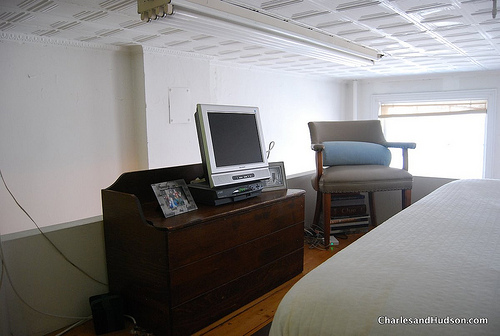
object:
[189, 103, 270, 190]
television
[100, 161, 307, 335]
dresser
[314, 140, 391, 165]
pillow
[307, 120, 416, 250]
chair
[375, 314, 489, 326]
name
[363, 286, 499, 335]
corner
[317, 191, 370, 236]
books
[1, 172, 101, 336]
wire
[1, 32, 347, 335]
wall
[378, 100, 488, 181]
window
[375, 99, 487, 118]
blinds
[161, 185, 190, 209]
picture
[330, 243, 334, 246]
light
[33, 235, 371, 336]
floor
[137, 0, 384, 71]
light fixture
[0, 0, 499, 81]
ceiling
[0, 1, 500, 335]
room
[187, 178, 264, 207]
cable box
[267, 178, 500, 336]
bed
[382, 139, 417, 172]
left armrest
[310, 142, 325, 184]
right armrest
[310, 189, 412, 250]
legs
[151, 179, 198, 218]
picture frame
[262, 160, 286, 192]
picture frame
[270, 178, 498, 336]
comforter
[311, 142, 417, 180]
armrests